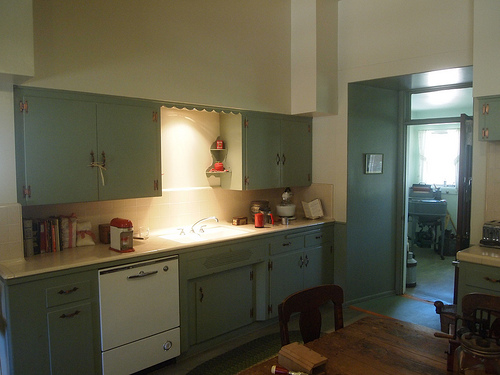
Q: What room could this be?
A: It is a kitchen.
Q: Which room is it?
A: It is a kitchen.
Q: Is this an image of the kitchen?
A: Yes, it is showing the kitchen.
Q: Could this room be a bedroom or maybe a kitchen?
A: It is a kitchen.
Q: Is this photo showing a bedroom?
A: No, the picture is showing a kitchen.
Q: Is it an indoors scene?
A: Yes, it is indoors.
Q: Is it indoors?
A: Yes, it is indoors.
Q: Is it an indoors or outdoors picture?
A: It is indoors.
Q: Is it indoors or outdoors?
A: It is indoors.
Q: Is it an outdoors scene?
A: No, it is indoors.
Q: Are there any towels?
A: No, there are no towels.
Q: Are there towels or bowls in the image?
A: No, there are no towels or bowls.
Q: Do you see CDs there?
A: No, there are no cds.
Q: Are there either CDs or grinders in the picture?
A: No, there are no CDs or grinders.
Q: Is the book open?
A: Yes, the book is open.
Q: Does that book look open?
A: Yes, the book is open.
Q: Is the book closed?
A: No, the book is open.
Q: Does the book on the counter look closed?
A: No, the book is open.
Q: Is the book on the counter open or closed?
A: The book is open.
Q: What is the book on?
A: The book is on the counter.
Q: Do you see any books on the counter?
A: Yes, there is a book on the counter.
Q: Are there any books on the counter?
A: Yes, there is a book on the counter.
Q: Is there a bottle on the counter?
A: No, there is a book on the counter.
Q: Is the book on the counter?
A: Yes, the book is on the counter.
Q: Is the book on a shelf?
A: No, the book is on the counter.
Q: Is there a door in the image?
A: Yes, there is a door.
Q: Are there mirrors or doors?
A: Yes, there is a door.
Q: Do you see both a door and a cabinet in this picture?
A: Yes, there are both a door and a cabinet.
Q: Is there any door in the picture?
A: Yes, there is a door.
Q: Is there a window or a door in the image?
A: Yes, there is a door.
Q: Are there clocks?
A: No, there are no clocks.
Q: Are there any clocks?
A: No, there are no clocks.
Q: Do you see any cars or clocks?
A: No, there are no clocks or cars.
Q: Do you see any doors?
A: Yes, there is a door.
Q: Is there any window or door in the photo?
A: Yes, there is a door.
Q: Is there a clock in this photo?
A: No, there are no clocks.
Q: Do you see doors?
A: Yes, there is a door.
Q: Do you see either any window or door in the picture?
A: Yes, there is a door.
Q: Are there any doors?
A: Yes, there is a door.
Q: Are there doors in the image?
A: Yes, there is a door.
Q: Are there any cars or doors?
A: Yes, there is a door.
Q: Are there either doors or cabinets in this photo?
A: Yes, there is a door.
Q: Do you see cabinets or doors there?
A: Yes, there is a door.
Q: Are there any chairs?
A: Yes, there is a chair.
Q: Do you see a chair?
A: Yes, there is a chair.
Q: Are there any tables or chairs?
A: Yes, there is a chair.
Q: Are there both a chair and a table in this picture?
A: Yes, there are both a chair and a table.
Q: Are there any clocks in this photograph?
A: No, there are no clocks.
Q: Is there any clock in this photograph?
A: No, there are no clocks.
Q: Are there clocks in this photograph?
A: No, there are no clocks.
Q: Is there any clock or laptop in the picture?
A: No, there are no clocks or laptops.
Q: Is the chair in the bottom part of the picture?
A: Yes, the chair is in the bottom of the image.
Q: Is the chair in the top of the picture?
A: No, the chair is in the bottom of the image.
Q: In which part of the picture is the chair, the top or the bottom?
A: The chair is in the bottom of the image.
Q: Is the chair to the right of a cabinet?
A: Yes, the chair is to the right of a cabinet.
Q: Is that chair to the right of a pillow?
A: No, the chair is to the right of a cabinet.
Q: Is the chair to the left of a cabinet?
A: No, the chair is to the right of a cabinet.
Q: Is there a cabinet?
A: Yes, there is a cabinet.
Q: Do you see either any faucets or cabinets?
A: Yes, there is a cabinet.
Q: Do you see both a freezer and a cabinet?
A: No, there is a cabinet but no refrigerators.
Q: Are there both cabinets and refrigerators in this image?
A: No, there is a cabinet but no refrigerators.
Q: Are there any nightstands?
A: No, there are no nightstands.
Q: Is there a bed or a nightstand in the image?
A: No, there are no nightstands or beds.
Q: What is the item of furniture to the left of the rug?
A: The piece of furniture is a cabinet.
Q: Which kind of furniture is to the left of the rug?
A: The piece of furniture is a cabinet.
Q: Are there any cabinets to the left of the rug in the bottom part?
A: Yes, there is a cabinet to the left of the rug.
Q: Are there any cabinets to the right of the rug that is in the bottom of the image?
A: No, the cabinet is to the left of the rug.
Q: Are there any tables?
A: Yes, there is a table.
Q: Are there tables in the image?
A: Yes, there is a table.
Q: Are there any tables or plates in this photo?
A: Yes, there is a table.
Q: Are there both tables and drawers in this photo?
A: Yes, there are both a table and a drawer.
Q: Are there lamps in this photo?
A: No, there are no lamps.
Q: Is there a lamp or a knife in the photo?
A: No, there are no lamps or knives.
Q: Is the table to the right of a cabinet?
A: Yes, the table is to the right of a cabinet.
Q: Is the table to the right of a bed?
A: No, the table is to the right of a cabinet.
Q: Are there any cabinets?
A: Yes, there is a cabinet.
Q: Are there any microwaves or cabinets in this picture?
A: Yes, there is a cabinet.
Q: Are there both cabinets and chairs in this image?
A: Yes, there are both a cabinet and a chair.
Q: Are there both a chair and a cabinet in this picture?
A: Yes, there are both a cabinet and a chair.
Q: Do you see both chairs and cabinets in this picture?
A: Yes, there are both a cabinet and a chair.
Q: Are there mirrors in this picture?
A: No, there are no mirrors.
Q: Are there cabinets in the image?
A: Yes, there is a cabinet.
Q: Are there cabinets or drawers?
A: Yes, there is a cabinet.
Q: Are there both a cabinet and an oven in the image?
A: No, there is a cabinet but no ovens.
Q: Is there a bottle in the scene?
A: No, there are no bottles.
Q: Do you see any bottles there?
A: No, there are no bottles.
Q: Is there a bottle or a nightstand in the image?
A: No, there are no bottles or nightstands.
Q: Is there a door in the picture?
A: Yes, there is a door.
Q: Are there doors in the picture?
A: Yes, there is a door.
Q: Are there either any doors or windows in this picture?
A: Yes, there is a door.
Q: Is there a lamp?
A: No, there are no lamps.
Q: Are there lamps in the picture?
A: No, there are no lamps.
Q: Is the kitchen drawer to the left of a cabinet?
A: No, the drawer is to the right of a cabinet.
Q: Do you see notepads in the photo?
A: No, there are no notepads.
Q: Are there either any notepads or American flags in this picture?
A: No, there are no notepads or American flags.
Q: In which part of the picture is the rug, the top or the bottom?
A: The rug is in the bottom of the image.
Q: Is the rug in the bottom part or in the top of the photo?
A: The rug is in the bottom of the image.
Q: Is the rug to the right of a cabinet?
A: Yes, the rug is to the right of a cabinet.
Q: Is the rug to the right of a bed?
A: No, the rug is to the right of a cabinet.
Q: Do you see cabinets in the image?
A: Yes, there is a cabinet.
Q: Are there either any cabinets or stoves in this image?
A: Yes, there is a cabinet.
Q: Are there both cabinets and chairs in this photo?
A: Yes, there are both a cabinet and a chair.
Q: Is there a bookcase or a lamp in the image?
A: No, there are no lamps or bookcases.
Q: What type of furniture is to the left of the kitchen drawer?
A: The piece of furniture is a cabinet.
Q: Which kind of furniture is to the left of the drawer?
A: The piece of furniture is a cabinet.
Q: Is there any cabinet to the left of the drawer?
A: Yes, there is a cabinet to the left of the drawer.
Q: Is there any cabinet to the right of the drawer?
A: No, the cabinet is to the left of the drawer.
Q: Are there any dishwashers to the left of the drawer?
A: No, there is a cabinet to the left of the drawer.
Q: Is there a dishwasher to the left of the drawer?
A: No, there is a cabinet to the left of the drawer.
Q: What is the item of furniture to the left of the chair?
A: The piece of furniture is a cabinet.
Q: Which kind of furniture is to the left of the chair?
A: The piece of furniture is a cabinet.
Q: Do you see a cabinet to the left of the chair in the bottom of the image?
A: Yes, there is a cabinet to the left of the chair.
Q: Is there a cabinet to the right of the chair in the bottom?
A: No, the cabinet is to the left of the chair.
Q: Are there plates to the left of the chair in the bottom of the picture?
A: No, there is a cabinet to the left of the chair.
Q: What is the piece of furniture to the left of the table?
A: The piece of furniture is a cabinet.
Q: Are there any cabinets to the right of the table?
A: No, the cabinet is to the left of the table.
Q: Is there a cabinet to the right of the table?
A: No, the cabinet is to the left of the table.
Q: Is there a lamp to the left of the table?
A: No, there is a cabinet to the left of the table.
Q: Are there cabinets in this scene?
A: Yes, there is a cabinet.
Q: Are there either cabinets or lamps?
A: Yes, there is a cabinet.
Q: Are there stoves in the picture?
A: No, there are no stoves.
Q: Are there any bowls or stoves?
A: No, there are no stoves or bowls.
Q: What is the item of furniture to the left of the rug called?
A: The piece of furniture is a cabinet.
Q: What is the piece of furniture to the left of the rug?
A: The piece of furniture is a cabinet.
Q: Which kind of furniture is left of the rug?
A: The piece of furniture is a cabinet.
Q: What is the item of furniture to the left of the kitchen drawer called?
A: The piece of furniture is a cabinet.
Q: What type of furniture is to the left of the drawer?
A: The piece of furniture is a cabinet.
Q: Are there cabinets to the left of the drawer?
A: Yes, there is a cabinet to the left of the drawer.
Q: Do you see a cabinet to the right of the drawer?
A: No, the cabinet is to the left of the drawer.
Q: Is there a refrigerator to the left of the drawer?
A: No, there is a cabinet to the left of the drawer.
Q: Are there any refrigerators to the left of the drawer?
A: No, there is a cabinet to the left of the drawer.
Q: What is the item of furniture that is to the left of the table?
A: The piece of furniture is a cabinet.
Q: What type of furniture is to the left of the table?
A: The piece of furniture is a cabinet.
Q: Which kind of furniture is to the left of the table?
A: The piece of furniture is a cabinet.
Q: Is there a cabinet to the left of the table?
A: Yes, there is a cabinet to the left of the table.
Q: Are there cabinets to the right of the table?
A: No, the cabinet is to the left of the table.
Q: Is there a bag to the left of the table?
A: No, there is a cabinet to the left of the table.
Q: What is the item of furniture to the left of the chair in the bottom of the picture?
A: The piece of furniture is a cabinet.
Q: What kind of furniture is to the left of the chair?
A: The piece of furniture is a cabinet.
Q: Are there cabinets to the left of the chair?
A: Yes, there is a cabinet to the left of the chair.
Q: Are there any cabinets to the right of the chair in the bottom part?
A: No, the cabinet is to the left of the chair.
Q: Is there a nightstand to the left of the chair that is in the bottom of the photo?
A: No, there is a cabinet to the left of the chair.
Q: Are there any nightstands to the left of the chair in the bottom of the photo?
A: No, there is a cabinet to the left of the chair.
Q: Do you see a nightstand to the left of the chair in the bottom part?
A: No, there is a cabinet to the left of the chair.